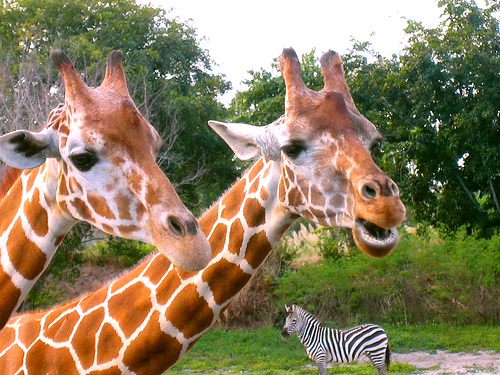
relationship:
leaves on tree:
[345, 32, 360, 43] [221, 18, 495, 236]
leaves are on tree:
[0, 0, 234, 214] [0, 0, 232, 266]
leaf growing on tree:
[144, 51, 147, 54] [133, 47, 183, 82]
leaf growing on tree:
[157, 56, 160, 61] [133, 47, 183, 82]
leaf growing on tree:
[160, 38, 164, 42] [133, 47, 183, 82]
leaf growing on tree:
[169, 46, 175, 50] [133, 47, 183, 82]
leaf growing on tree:
[160, 68, 165, 70] [133, 47, 183, 82]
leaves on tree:
[442, 185, 464, 217] [378, 80, 493, 207]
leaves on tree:
[415, 75, 438, 100] [361, 40, 498, 218]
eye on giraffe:
[278, 140, 310, 159] [10, 58, 413, 365]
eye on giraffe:
[366, 135, 384, 155] [10, 58, 413, 365]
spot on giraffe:
[243, 230, 272, 268] [10, 58, 413, 365]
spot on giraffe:
[242, 194, 267, 228] [3, 43, 403, 371]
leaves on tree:
[165, 77, 203, 117] [161, 56, 251, 200]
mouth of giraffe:
[360, 214, 401, 247] [0, 87, 408, 374]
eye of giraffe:
[278, 140, 309, 161] [187, 36, 416, 298]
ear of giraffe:
[0, 128, 55, 172] [7, 31, 222, 276]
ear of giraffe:
[211, 120, 259, 160] [164, 60, 379, 351]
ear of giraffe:
[2, 121, 55, 168] [12, 100, 197, 305]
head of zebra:
[275, 301, 307, 340] [278, 302, 395, 374]